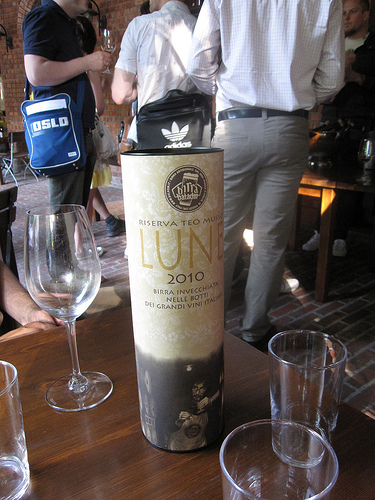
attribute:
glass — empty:
[13, 203, 107, 348]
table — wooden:
[297, 170, 373, 305]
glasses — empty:
[25, 201, 180, 424]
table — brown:
[23, 317, 324, 493]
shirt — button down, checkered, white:
[180, 3, 358, 125]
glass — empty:
[268, 328, 342, 465]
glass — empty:
[218, 419, 339, 496]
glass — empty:
[0, 363, 27, 498]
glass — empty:
[18, 186, 111, 329]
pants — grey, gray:
[212, 109, 309, 332]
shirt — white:
[127, 25, 205, 93]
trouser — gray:
[221, 121, 287, 218]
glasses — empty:
[1, 200, 372, 495]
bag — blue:
[20, 93, 88, 174]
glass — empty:
[24, 201, 115, 415]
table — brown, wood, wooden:
[0, 301, 373, 498]